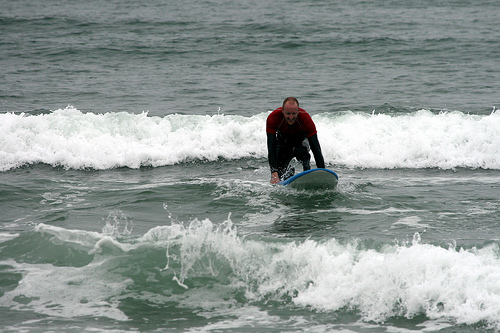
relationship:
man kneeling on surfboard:
[264, 95, 327, 186] [281, 167, 341, 195]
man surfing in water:
[264, 95, 327, 186] [1, 1, 500, 332]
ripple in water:
[116, 24, 188, 37] [1, 1, 500, 332]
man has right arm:
[264, 95, 327, 186] [265, 113, 286, 189]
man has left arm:
[264, 95, 327, 186] [301, 111, 328, 170]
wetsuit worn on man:
[263, 108, 327, 178] [264, 95, 327, 186]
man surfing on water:
[264, 95, 327, 186] [1, 1, 500, 332]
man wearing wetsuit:
[264, 95, 327, 186] [263, 108, 327, 178]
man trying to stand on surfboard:
[264, 95, 327, 186] [281, 167, 341, 195]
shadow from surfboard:
[276, 189, 338, 245] [281, 167, 341, 195]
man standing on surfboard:
[264, 95, 327, 186] [281, 167, 341, 195]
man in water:
[264, 95, 327, 186] [1, 1, 500, 332]